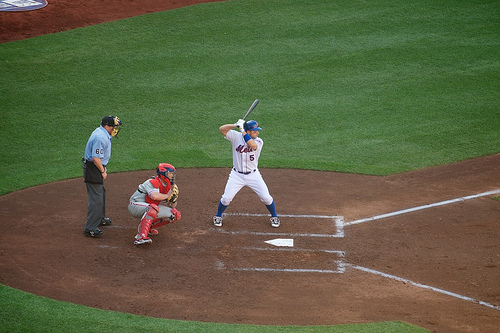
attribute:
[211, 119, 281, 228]
players — ready, dressed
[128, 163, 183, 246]
catcher — dressed, dressed in red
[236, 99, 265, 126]
bat — black, raised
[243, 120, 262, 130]
helmet — blue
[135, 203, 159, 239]
shin guards — protective, protection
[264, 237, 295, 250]
home plate — white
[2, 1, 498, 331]
grass — green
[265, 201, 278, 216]
socks — blue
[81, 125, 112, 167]
shirt — blue, gray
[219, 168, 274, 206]
trousers — white